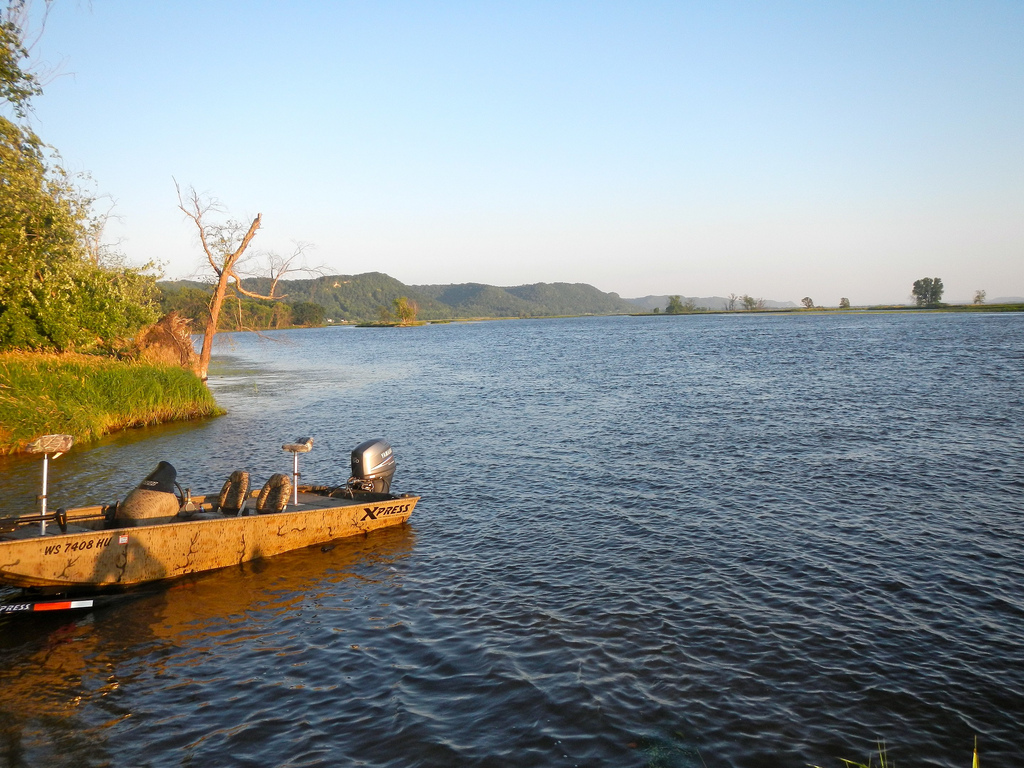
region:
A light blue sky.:
[5, 7, 1020, 305]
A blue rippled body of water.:
[3, 323, 1019, 764]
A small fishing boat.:
[0, 429, 422, 617]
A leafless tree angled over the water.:
[163, 176, 335, 382]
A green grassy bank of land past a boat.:
[0, 339, 226, 457]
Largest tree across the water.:
[911, 273, 944, 309]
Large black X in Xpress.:
[359, 506, 379, 526]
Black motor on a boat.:
[346, 437, 401, 495]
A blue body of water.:
[7, 318, 1022, 765]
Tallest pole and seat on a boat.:
[27, 431, 75, 533]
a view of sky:
[391, 82, 585, 203]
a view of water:
[572, 620, 750, 734]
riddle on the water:
[640, 693, 774, 752]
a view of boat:
[170, 451, 477, 589]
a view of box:
[345, 426, 404, 500]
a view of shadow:
[72, 546, 196, 652]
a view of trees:
[145, 274, 273, 372]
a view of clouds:
[645, 107, 808, 245]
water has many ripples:
[520, 332, 983, 681]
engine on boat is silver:
[356, 427, 430, 485]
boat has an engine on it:
[349, 409, 441, 530]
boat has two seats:
[216, 458, 311, 534]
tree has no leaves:
[183, 175, 333, 343]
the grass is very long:
[11, 360, 212, 441]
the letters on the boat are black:
[358, 500, 423, 530]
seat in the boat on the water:
[209, 461, 251, 520]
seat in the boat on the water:
[256, 470, 296, 515]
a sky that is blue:
[242, 28, 560, 180]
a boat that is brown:
[90, 449, 435, 571]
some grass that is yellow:
[84, 394, 206, 443]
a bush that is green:
[23, 183, 186, 390]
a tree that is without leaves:
[169, 201, 329, 367]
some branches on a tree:
[166, 203, 259, 273]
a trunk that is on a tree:
[187, 280, 245, 370]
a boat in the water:
[0, 358, 468, 650]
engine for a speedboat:
[326, 417, 415, 517]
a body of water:
[24, 240, 1017, 719]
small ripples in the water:
[469, 585, 830, 707]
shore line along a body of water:
[16, 220, 865, 468]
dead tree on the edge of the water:
[160, 151, 306, 417]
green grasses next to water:
[7, 326, 216, 438]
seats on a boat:
[200, 455, 308, 535]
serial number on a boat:
[29, 535, 138, 554]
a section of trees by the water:
[0, 160, 174, 360]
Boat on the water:
[24, 404, 410, 604]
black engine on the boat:
[347, 429, 409, 496]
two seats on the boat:
[212, 470, 307, 522]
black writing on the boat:
[35, 537, 125, 560]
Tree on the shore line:
[173, 173, 297, 409]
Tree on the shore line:
[904, 268, 950, 313]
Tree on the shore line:
[654, 294, 703, 317]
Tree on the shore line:
[375, 294, 424, 330]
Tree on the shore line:
[287, 291, 338, 331]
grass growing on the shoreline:
[3, 341, 223, 463]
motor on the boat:
[348, 416, 405, 502]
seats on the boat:
[216, 465, 295, 522]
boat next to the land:
[4, 432, 419, 584]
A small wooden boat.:
[3, 431, 415, 618]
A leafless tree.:
[167, 175, 313, 379]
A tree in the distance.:
[970, 285, 987, 308]